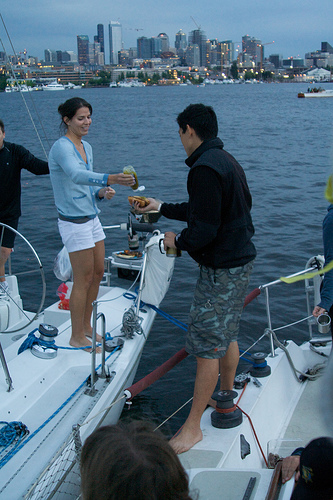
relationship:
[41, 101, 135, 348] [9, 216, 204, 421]
woman standing on boat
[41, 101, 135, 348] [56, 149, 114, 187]
woman has longsleeve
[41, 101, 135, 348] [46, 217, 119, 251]
woman has shorts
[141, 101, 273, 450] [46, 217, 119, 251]
man has shorts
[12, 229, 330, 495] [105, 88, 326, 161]
boats in ocean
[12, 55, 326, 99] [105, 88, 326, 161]
slyline next to ocean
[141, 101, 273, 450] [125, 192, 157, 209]
man holding bun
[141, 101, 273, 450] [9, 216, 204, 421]
man standing on boat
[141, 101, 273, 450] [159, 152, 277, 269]
man has jacket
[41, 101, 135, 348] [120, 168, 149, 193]
woman putting relish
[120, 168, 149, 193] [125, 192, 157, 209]
relish on bun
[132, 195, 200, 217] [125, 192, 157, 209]
hand holding bun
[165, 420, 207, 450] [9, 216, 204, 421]
foot standing on boat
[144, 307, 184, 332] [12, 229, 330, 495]
rope between boats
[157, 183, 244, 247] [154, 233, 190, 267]
hand holding silvermug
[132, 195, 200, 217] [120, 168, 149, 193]
hand holding rellish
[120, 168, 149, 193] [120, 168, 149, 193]
bottle of rellish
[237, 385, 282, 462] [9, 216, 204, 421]
redrope on boat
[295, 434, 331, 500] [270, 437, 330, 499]
hat on head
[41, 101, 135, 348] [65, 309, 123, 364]
woman has barefeet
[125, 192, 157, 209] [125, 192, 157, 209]
bun and bun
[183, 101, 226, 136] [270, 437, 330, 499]
back of head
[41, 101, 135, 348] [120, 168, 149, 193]
woman putting rellish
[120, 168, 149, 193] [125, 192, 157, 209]
rellish on bun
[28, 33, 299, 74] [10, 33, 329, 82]
buildings in background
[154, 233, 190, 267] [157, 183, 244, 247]
silvermug on hand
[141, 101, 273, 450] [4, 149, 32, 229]
man wearing black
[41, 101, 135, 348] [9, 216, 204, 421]
woman on boat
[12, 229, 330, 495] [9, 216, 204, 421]
people on boat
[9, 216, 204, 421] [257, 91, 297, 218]
boat in water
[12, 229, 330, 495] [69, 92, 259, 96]
boats on river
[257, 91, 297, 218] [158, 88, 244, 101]
water on river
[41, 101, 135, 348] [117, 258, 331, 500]
woman standing on boat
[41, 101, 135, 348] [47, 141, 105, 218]
woman wearing shirt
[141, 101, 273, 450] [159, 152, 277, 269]
man wearing jacket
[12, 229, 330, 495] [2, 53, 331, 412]
boats docked at marina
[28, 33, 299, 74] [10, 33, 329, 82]
citylights in distance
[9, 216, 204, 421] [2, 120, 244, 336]
boat with people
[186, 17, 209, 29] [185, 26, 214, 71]
crane on bulding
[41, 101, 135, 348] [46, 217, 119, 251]
woman wearing shorts